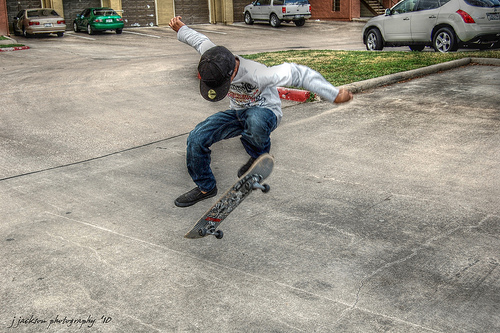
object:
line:
[123, 28, 160, 38]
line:
[66, 32, 95, 41]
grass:
[313, 53, 405, 68]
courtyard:
[13, 31, 495, 329]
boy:
[165, 14, 354, 208]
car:
[362, 0, 500, 56]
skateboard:
[182, 153, 273, 240]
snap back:
[168, 12, 354, 240]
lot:
[1, 32, 493, 332]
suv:
[240, 0, 317, 30]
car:
[71, 9, 126, 37]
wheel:
[214, 230, 224, 240]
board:
[183, 156, 276, 238]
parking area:
[8, 19, 412, 55]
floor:
[17, 38, 493, 329]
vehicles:
[13, 4, 66, 41]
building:
[0, 0, 390, 33]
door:
[117, 0, 157, 27]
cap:
[197, 46, 237, 103]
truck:
[198, 219, 225, 246]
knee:
[248, 118, 265, 132]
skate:
[180, 153, 274, 242]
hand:
[335, 89, 353, 104]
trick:
[162, 150, 279, 238]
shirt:
[175, 26, 340, 130]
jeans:
[187, 108, 277, 193]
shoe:
[174, 182, 217, 208]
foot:
[174, 185, 218, 208]